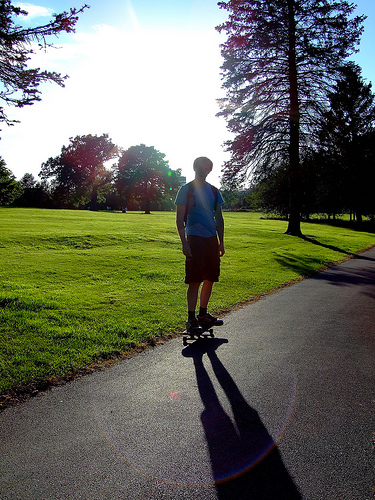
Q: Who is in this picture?
A: One man.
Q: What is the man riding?
A: A skateboard.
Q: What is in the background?
A: A field.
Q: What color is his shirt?
A: Blue.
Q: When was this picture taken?
A: Broad daylight.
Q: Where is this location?
A: A park.